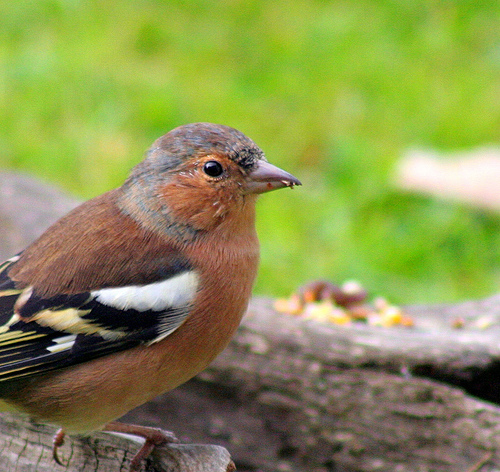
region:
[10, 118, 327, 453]
orange bird with black and white wings perched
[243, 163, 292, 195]
bird's beak contains blood and other animal remains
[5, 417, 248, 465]
bird pereched of grey rock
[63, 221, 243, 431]
bird has yellow and o\range Coke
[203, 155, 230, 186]
small round black eye on bird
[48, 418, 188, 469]
orange feet of bird on grey bench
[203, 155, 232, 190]
Eye of a bird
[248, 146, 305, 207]
Beak of a bird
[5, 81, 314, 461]
The bird if sitting on a tree log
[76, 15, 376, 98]
Patch of green grass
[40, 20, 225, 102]
Patch of dark green grass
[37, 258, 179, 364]
Gold, black and white colored feathers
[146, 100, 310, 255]
Head of a bird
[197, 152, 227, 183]
Black colored eye of a bird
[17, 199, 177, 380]
Feathers on a bird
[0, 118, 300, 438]
a little black eyed bird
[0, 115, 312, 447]
wings with black white and orange patterns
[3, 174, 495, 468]
a log with a bird on it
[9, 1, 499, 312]
a blurry ground covered in leaves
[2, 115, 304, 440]
a tiny bird standing on wood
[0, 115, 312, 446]
an orange bird with a gray beak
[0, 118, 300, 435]
a bird sitting on a tree branch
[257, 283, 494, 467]
a log with a cracked hole on it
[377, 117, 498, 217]
a blurry foot in the leaves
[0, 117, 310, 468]
a bird perched on a tree limb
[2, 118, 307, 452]
a small bird with black eyes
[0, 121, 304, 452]
a little gray tipped beak bird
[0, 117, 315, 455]
a bird with a patterned wing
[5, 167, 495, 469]
a log with a bird on it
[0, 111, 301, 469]
a small bird on a wooden ledge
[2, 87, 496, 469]
a large tree branch with a bird nested on it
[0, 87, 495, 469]
a small bird perched on a tree branch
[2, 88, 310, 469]
an animal sitting on a tree limb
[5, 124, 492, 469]
a tree limb with a bird rested on it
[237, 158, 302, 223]
bird has grey beak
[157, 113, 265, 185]
bird has grey head